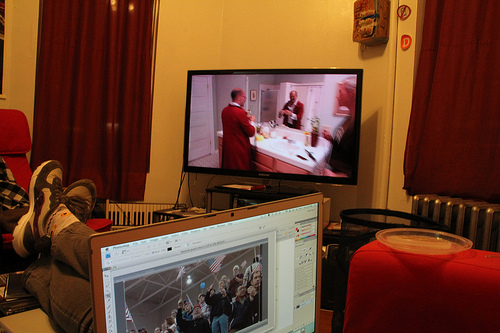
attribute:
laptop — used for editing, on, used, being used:
[88, 190, 325, 331]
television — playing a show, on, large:
[184, 68, 364, 186]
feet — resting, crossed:
[11, 156, 99, 257]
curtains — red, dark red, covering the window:
[30, 1, 154, 203]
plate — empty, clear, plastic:
[376, 225, 475, 257]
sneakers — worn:
[11, 159, 97, 256]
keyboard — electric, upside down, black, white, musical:
[94, 196, 186, 230]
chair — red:
[0, 109, 115, 255]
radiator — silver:
[407, 195, 499, 253]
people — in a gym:
[112, 235, 268, 330]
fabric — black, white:
[0, 157, 29, 232]